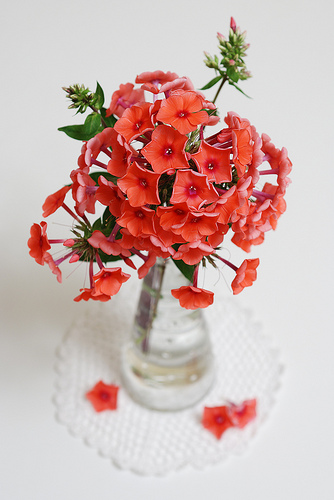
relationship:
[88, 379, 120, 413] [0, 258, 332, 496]
flower sitting on ground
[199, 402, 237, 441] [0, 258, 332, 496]
flower sitting on ground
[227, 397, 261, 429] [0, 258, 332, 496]
flower sitting on ground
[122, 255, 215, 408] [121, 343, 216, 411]
flower vase filled with water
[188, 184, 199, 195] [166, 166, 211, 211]
purple inside flower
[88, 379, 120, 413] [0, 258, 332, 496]
flower on table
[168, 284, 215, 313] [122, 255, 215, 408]
flower in flower vase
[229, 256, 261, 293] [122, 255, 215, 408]
flower in flower vase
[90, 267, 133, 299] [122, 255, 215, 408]
flower in flower vase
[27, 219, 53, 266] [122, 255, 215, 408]
flower in flower vase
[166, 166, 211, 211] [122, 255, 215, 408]
flower in flower vase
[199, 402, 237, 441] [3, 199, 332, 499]
petal placed on table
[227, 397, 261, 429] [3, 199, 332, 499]
petal placed on table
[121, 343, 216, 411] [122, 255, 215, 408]
water placed inside flower vase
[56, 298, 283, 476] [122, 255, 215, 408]
doylie under flower vase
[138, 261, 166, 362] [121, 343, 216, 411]
stem inside of water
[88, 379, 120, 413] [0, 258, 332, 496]
flower placed on ground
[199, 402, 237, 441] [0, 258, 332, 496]
flower placed on ground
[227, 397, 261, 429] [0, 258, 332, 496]
flower placed on ground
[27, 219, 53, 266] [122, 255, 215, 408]
flower inside flower vase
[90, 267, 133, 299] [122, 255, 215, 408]
flower inside flower vase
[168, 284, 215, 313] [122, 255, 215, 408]
flower inside flower vase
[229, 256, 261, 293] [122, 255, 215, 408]
flower inside flower vase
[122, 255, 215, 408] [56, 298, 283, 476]
flower vase on doylie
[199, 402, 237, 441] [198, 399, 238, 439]
flower has fallen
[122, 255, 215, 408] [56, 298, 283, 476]
flower vase sitting on doylie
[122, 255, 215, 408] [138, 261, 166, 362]
flower vase with stem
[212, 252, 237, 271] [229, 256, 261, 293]
strand extending from flower